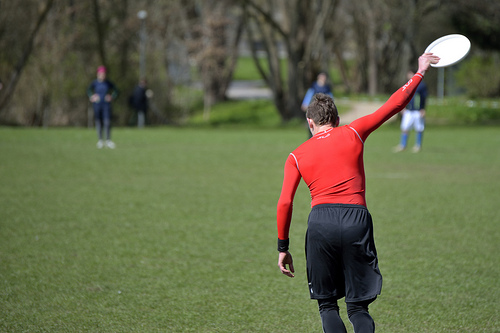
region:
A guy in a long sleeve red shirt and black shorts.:
[276, 50, 441, 332]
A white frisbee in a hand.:
[420, 32, 471, 66]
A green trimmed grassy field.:
[1, 122, 499, 329]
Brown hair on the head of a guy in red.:
[306, 91, 338, 126]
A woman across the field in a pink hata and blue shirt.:
[90, 65, 117, 150]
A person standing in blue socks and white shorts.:
[393, 66, 427, 153]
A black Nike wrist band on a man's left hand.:
[274, 235, 290, 252]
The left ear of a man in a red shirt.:
[305, 114, 314, 128]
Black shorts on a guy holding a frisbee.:
[300, 203, 383, 305]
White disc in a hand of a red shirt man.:
[421, 33, 472, 65]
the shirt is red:
[285, 140, 408, 213]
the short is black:
[300, 206, 387, 301]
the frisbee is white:
[426, 35, 475, 66]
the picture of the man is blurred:
[78, 58, 138, 158]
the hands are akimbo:
[76, 84, 121, 109]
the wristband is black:
[271, 235, 298, 253]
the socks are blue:
[393, 132, 429, 151]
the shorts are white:
[398, 110, 427, 132]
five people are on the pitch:
[60, 49, 448, 330]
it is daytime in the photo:
[3, 5, 474, 325]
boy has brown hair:
[280, 90, 348, 138]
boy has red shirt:
[251, 71, 435, 268]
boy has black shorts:
[305, 210, 373, 311]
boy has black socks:
[322, 274, 373, 331]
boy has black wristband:
[272, 214, 299, 255]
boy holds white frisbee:
[402, 1, 469, 91]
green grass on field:
[61, 223, 195, 331]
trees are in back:
[50, 0, 281, 110]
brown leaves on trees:
[42, 13, 236, 80]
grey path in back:
[234, 77, 404, 145]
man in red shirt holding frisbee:
[273, 28, 474, 331]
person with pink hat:
[88, 62, 121, 155]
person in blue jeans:
[393, 64, 433, 155]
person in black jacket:
[129, 69, 152, 131]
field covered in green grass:
[7, 125, 499, 331]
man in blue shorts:
[293, 185, 380, 306]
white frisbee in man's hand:
[414, 27, 471, 78]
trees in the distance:
[5, 2, 497, 151]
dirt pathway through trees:
[336, 79, 393, 136]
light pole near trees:
[130, 3, 152, 131]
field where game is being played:
[8, 125, 477, 310]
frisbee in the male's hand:
[262, 18, 459, 325]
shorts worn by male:
[293, 206, 382, 301]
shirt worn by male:
[268, 70, 405, 206]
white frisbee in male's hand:
[415, 33, 473, 66]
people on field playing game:
[90, 68, 447, 156]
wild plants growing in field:
[413, 89, 495, 124]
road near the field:
[344, 94, 391, 124]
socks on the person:
[398, 130, 430, 145]